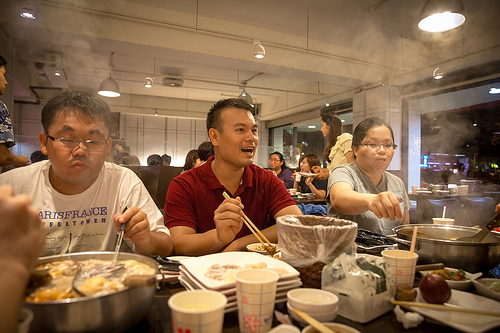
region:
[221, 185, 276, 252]
a piar of chopsticks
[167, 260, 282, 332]
paper cups on the table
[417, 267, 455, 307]
a red apple on the table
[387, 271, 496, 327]
a white plate on the table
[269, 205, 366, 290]
a plastic bag in the basket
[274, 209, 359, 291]
a trash can on the table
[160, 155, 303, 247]
a red collered shirt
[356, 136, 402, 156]
glasses on her face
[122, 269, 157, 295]
handle of the ladle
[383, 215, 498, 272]
a pan on the stove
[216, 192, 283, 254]
A wooden pair of chopsticks.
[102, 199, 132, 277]
A metal serving spoon.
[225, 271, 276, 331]
A paper cup with a design on it.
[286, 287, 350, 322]
Small white bowls stacked.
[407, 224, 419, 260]
A light colored straw.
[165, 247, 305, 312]
A stack of white square plates.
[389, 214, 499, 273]
A silver pot on the table.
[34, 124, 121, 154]
A pair of glasses.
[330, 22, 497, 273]
Steam coming from a pot.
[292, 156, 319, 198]
A woman sitting down and drinking.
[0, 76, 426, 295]
people sitting at a table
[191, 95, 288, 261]
man holding chopsticks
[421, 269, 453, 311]
a red apple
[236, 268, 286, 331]
a plastic cup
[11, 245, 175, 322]
a bowl of soup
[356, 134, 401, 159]
woman wearing glasses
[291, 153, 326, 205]
woman sipping a drink from a plastic cup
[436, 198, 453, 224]
a white straw in a plastic cup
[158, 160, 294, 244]
man wearing a red polo shirt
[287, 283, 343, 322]
a stack of small white bowls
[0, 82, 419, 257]
three people seated next to each other during a meal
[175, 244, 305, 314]
stack of white plates on a table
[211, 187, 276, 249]
right hand holding a pair of chopsticks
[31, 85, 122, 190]
man's face with eyeglasses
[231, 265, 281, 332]
paper cup with blue perpendicular lines and flowers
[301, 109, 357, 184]
female waitress attending to her table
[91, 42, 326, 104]
overhead lighting attached to a ceiling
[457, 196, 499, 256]
utensil being stirred with a human hand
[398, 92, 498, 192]
large window showing it is evening outdoors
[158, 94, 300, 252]
man in red shirt with semi-open mouth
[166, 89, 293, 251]
Man is holding chopsticks.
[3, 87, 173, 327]
Man is putting spoon in bowl.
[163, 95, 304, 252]
Man is wearing red a shirt.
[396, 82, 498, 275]
Steam is rising from the bowl.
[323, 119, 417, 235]
Woman is wearing a gray shirt.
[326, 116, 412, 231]
Woman is wearing glasses.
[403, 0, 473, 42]
Light is turned on.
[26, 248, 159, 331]
Bowl is filled with food.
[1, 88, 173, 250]
Man is looking at bowl.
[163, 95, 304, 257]
Man is speaking to someone.